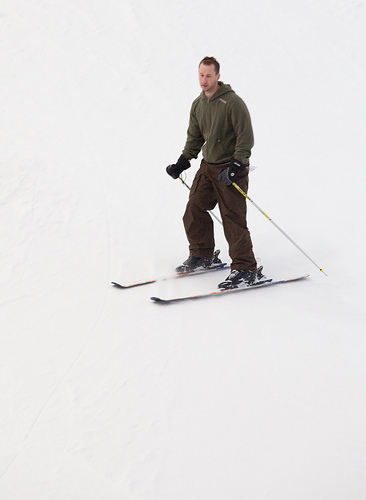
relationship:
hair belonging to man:
[195, 55, 219, 71] [164, 56, 258, 291]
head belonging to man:
[194, 56, 221, 92] [164, 56, 258, 291]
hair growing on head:
[195, 55, 219, 71] [194, 56, 221, 92]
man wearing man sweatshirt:
[164, 56, 258, 291] [179, 80, 253, 169]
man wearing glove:
[161, 51, 266, 295] [165, 154, 191, 179]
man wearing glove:
[161, 51, 266, 295] [214, 157, 245, 186]